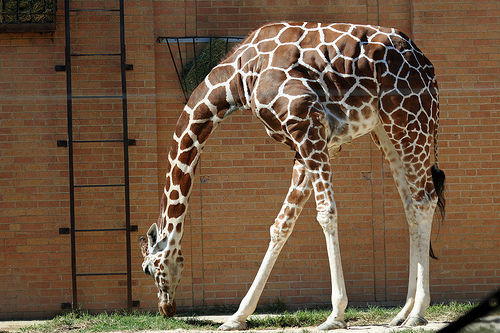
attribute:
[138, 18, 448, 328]
giraffe — bending over, spotted, brown, tan, white, long, grazing, eating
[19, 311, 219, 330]
grass — small, green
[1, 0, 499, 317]
wall — brick, red, large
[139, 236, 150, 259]
horns — black tipped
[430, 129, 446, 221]
tail — black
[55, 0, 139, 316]
ladder — metal, black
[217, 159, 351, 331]
legs — white, extended